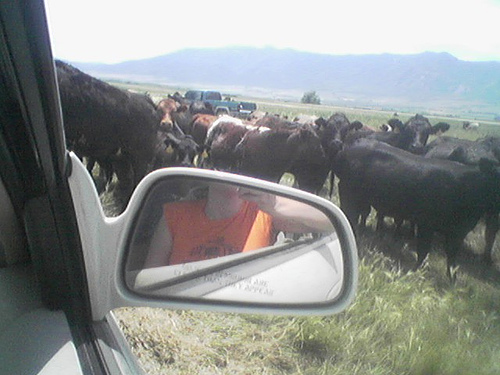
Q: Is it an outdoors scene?
A: Yes, it is outdoors.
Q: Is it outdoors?
A: Yes, it is outdoors.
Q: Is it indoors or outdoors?
A: It is outdoors.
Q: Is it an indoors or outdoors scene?
A: It is outdoors.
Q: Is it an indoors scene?
A: No, it is outdoors.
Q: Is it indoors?
A: No, it is outdoors.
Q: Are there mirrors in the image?
A: Yes, there is a mirror.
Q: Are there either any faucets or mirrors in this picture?
A: Yes, there is a mirror.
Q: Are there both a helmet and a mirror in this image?
A: No, there is a mirror but no helmets.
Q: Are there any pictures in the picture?
A: No, there are no pictures.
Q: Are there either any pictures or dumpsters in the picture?
A: No, there are no pictures or dumpsters.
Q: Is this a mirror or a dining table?
A: This is a mirror.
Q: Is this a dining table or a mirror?
A: This is a mirror.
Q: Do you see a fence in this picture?
A: No, there are no fences.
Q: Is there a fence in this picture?
A: No, there are no fences.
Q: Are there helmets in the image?
A: No, there are no helmets.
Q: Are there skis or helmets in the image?
A: No, there are no helmets or skis.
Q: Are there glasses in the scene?
A: No, there are no glasses.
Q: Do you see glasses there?
A: No, there are no glasses.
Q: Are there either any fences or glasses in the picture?
A: No, there are no glasses or fences.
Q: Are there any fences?
A: No, there are no fences.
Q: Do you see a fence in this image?
A: No, there are no fences.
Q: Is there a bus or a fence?
A: No, there are no fences or buses.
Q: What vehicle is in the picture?
A: The vehicle is a car.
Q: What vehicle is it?
A: The vehicle is a car.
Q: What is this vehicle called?
A: That is a car.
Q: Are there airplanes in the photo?
A: No, there are no airplanes.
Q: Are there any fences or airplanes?
A: No, there are no airplanes or fences.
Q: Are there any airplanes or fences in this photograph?
A: No, there are no airplanes or fences.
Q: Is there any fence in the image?
A: No, there are no fences.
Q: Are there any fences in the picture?
A: No, there are no fences.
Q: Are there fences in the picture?
A: No, there are no fences.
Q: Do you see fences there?
A: No, there are no fences.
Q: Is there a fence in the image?
A: No, there are no fences.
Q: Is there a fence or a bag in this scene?
A: No, there are no fences or bags.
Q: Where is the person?
A: The person is in the car.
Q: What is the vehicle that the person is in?
A: The vehicle is a car.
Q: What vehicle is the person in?
A: The person is in the car.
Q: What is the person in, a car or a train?
A: The person is in a car.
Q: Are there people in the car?
A: Yes, there is a person in the car.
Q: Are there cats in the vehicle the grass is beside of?
A: No, there is a person in the car.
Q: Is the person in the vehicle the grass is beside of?
A: Yes, the person is in the car.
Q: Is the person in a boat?
A: No, the person is in the car.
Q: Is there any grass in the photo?
A: Yes, there is grass.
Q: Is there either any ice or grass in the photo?
A: Yes, there is grass.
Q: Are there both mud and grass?
A: No, there is grass but no mud.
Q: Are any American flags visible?
A: No, there are no American flags.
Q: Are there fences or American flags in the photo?
A: No, there are no American flags or fences.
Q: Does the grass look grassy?
A: Yes, the grass is grassy.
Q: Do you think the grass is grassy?
A: Yes, the grass is grassy.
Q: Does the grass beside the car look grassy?
A: Yes, the grass is grassy.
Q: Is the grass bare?
A: No, the grass is grassy.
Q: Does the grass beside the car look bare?
A: No, the grass is grassy.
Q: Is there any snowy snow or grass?
A: No, there is grass but it is grassy.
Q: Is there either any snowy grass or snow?
A: No, there is grass but it is grassy.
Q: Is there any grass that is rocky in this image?
A: No, there is grass but it is grassy.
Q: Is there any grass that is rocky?
A: No, there is grass but it is grassy.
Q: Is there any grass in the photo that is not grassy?
A: No, there is grass but it is grassy.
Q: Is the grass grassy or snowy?
A: The grass is grassy.